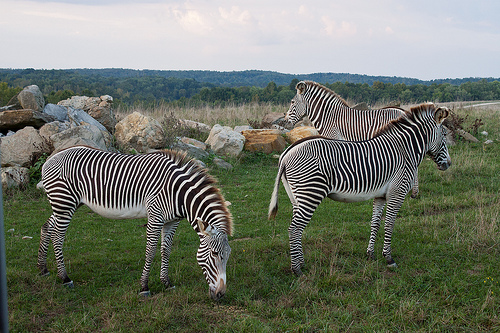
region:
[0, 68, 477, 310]
three zebras standing on flat field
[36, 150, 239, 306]
zebra eating grass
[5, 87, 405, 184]
large pile of rocks behind zebras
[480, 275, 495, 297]
yellow flowers among grass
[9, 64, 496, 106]
hills covered with trees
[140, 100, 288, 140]
tall brown grass behind rocks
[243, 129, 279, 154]
an orange colored rock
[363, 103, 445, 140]
black and white zebra mane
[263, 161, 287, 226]
white and brown zebra tail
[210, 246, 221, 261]
right eye of zebra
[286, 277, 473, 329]
green grass on the ground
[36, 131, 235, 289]
zebra grazing on the grass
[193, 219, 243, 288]
the head of a giraffe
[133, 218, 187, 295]
legs of a giraffe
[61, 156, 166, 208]
black and white stripes on a zebra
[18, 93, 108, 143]
rocks behind the zebras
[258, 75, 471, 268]
two zebras standing up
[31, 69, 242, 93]
mountains in the background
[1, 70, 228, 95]
large trees in the background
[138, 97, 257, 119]
brown grass growing from ground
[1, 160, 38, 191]
large rock in field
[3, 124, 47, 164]
large rock in field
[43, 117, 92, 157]
large rock in field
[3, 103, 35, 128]
large rock in field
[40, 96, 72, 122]
large rock in field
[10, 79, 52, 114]
large rock in field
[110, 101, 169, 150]
large rock in field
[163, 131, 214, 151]
large rock in field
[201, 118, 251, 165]
large rock in field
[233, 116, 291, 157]
large rock in field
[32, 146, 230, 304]
one zebra eating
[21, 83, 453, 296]
three zebras eating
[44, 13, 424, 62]
the sky in the background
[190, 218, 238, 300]
the head of the zebra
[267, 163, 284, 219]
the tail of this zebra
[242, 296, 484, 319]
some grass on the ground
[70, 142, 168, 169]
the back of the zebra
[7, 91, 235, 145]
several big rocks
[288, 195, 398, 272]
the four legs of this zebra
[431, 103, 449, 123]
the two ears of the zebra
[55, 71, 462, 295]
black and white zebras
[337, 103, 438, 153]
black and white mane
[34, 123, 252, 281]
zebra is eating grass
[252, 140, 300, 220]
black and white tail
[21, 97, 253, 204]
grey rocks behind zebras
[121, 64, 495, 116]
green trees in distance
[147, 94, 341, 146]
brown grass behind rocks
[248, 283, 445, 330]
wiry strands of grass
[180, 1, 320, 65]
blue and white sky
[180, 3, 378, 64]
thick and layered clouds